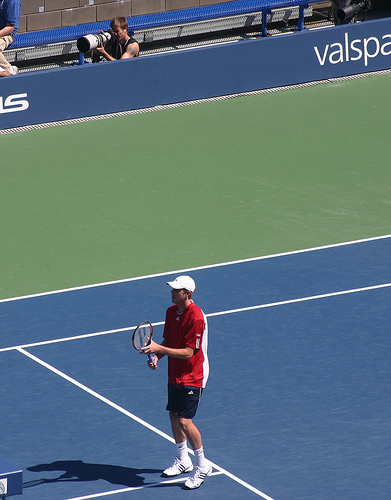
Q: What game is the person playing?
A: Tennis.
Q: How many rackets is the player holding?
A: One.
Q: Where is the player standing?
A: On the court.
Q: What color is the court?
A: Blue.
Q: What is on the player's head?
A: A hat.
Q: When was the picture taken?
A: Daytime.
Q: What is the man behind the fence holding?
A: A camera.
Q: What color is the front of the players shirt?
A: Red.